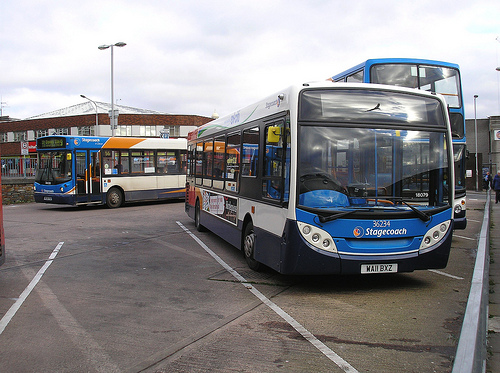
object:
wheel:
[240, 219, 266, 271]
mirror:
[260, 123, 282, 151]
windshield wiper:
[316, 205, 374, 224]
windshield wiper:
[397, 195, 431, 222]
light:
[310, 230, 321, 244]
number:
[385, 219, 391, 230]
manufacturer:
[350, 225, 408, 238]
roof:
[20, 96, 159, 122]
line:
[175, 222, 363, 373]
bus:
[33, 130, 188, 208]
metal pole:
[108, 48, 117, 135]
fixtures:
[112, 39, 127, 50]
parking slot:
[0, 220, 360, 373]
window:
[299, 125, 450, 207]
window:
[263, 122, 290, 198]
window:
[243, 124, 258, 174]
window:
[224, 133, 241, 181]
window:
[193, 141, 200, 183]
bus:
[322, 57, 465, 231]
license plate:
[360, 259, 400, 277]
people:
[490, 170, 500, 203]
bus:
[183, 78, 458, 283]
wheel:
[106, 185, 128, 209]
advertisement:
[199, 189, 241, 229]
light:
[96, 43, 111, 52]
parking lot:
[0, 177, 496, 372]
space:
[0, 211, 342, 371]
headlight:
[299, 223, 314, 236]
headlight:
[420, 237, 432, 247]